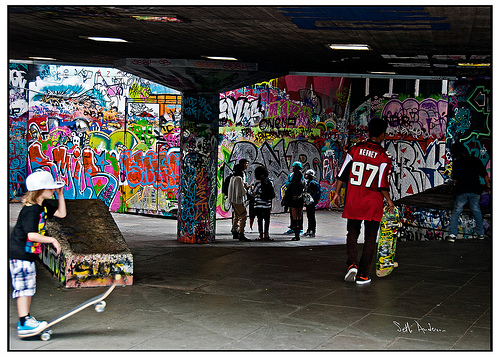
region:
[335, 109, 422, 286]
boy in red shirt holding a skateboard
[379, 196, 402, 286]
skateboard in boys hand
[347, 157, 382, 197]
number on the back of red shirt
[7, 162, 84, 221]
smaller boy wearing a cap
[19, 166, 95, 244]
smaller boy holding his cap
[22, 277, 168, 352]
skateboard being tipped up by smaller boy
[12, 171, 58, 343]
boy standing on one end of the skateboard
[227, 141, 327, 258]
group of children standing next to a pillar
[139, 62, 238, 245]
pillar next to group of children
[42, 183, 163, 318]
stone ramp next to small boy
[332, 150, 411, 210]
97 on the back of his shirt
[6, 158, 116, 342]
kid standing on the back of a skateboard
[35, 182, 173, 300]
ramp for skateboarding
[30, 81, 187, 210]
graffiti on the walls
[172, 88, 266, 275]
graffiti on the pole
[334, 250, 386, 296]
red stripes on boy's sneakers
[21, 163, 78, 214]
kid is wearing a white ball cap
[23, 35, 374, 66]
lights in the ceiling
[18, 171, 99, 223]
kid has long hair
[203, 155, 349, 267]
five people talking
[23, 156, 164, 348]
the kid is skateboarding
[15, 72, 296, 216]
graffitis on the wall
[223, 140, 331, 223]
group of kids are talking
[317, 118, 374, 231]
the jersey number is 97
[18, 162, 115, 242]
the kid is wearing a hat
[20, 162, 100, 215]
the hat is white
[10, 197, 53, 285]
the shirt is black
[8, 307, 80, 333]
the shoes are blue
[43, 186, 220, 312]
the ramp has graffiti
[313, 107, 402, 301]
boy holding a skateboard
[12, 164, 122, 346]
child wearing black shirt and blue shoes on skateboard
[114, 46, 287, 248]
concrete support pillar covered in graffiti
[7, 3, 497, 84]
ceiling with skylights and light graffiti on it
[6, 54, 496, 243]
walkway wall coated with tons of graffiti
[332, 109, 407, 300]
man in red jersey carrying yellow skateboard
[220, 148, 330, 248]
group of children standing on walkway and talking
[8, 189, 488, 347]
tiled stone urban walkway floor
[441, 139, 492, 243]
man in black shirt and jeans sitting on ledge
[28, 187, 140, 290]
large concrete slab covered with graffiti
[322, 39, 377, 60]
square skylight with bright light shining through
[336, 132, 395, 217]
boy wearing a red and white jersey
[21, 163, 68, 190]
girl wearing a white hat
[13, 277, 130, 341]
girl holding a skateboard up with her feet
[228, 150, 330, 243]
people standing by a graffiti wall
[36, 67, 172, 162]
colorful graffiti on a wall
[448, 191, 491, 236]
person wearing blue jeans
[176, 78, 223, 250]
a column covered in graffiti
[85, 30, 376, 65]
square lights on a ceiling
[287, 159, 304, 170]
person wearing a blue hat